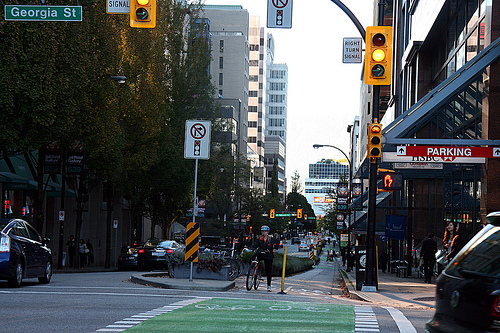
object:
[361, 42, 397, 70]
light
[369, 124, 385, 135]
light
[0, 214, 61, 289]
car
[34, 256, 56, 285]
wheel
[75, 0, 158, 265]
tree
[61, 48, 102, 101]
branches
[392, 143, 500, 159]
banner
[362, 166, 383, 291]
post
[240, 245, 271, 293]
bike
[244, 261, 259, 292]
wheel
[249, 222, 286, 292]
person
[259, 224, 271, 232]
helmet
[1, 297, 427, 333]
road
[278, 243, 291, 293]
post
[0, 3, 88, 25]
sign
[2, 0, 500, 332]
city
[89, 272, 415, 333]
crosswalk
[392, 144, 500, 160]
sign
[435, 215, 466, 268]
lady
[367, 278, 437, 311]
corner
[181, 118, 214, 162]
sign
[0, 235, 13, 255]
lights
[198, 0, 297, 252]
building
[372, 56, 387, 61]
part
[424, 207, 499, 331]
back